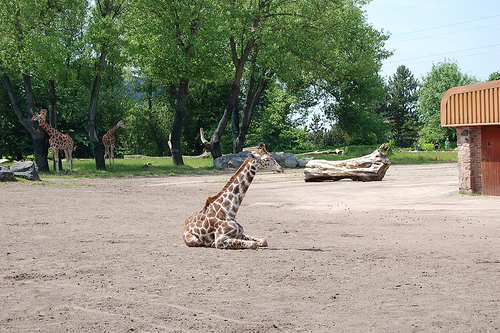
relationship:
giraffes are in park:
[24, 101, 288, 255] [1, 0, 500, 332]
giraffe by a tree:
[28, 104, 83, 173] [0, 2, 89, 178]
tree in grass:
[0, 2, 89, 178] [26, 154, 189, 179]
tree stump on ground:
[296, 144, 403, 186] [97, 147, 474, 332]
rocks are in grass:
[206, 141, 312, 179] [133, 141, 445, 170]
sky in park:
[363, 4, 499, 79] [1, 0, 500, 332]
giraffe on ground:
[170, 138, 288, 257] [97, 147, 474, 332]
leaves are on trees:
[12, 10, 310, 87] [1, 1, 273, 165]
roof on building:
[434, 86, 498, 125] [439, 79, 500, 192]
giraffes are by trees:
[21, 104, 144, 176] [1, 1, 273, 165]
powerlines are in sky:
[384, 17, 499, 62] [363, 4, 499, 79]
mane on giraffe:
[206, 148, 259, 195] [170, 138, 288, 257]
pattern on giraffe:
[201, 199, 240, 238] [170, 138, 288, 257]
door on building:
[480, 127, 499, 194] [439, 79, 500, 192]